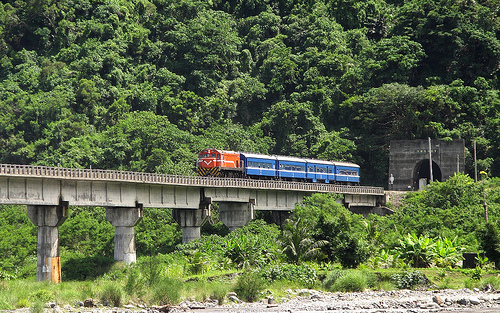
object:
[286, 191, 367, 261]
tree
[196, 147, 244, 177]
engine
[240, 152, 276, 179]
train car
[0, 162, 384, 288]
bridge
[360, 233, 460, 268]
bush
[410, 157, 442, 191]
archway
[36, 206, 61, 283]
pole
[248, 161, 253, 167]
window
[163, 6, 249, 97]
tree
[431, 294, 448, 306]
rock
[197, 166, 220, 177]
bumper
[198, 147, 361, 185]
train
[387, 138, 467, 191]
tunnel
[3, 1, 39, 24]
mountains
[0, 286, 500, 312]
gravel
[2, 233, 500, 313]
ground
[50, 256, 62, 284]
door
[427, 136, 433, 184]
pole